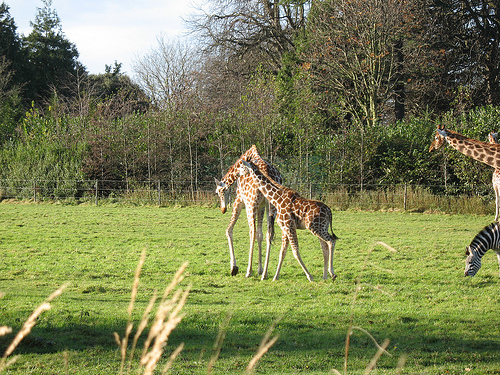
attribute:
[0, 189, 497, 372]
grass — green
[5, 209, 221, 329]
grass — short, green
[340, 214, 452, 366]
grass — green, short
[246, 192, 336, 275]
giraffe — adult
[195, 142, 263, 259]
giraffe — young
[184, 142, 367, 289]
giraffe — black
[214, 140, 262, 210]
neck — bent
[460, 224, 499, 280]
zebra — black, white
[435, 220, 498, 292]
zebra — brown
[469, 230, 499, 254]
stripes — black and white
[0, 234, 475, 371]
grasses — golden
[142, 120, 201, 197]
trunks — slender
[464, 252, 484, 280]
head — sticking out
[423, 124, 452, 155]
head — sticking out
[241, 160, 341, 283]
animal — yellow, brown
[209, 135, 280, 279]
animal — yellow, brown